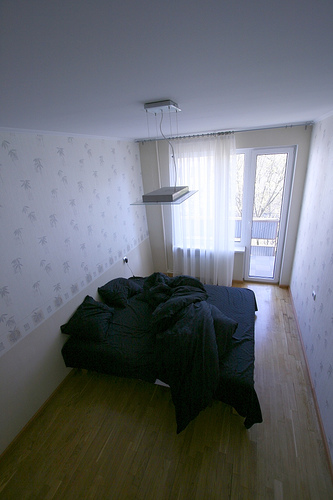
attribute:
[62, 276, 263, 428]
bed — black, unmade, king size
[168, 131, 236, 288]
curtain — white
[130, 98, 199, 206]
light fixture — hanging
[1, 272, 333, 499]
floor — hardwood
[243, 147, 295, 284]
door — glass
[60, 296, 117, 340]
pillow — black